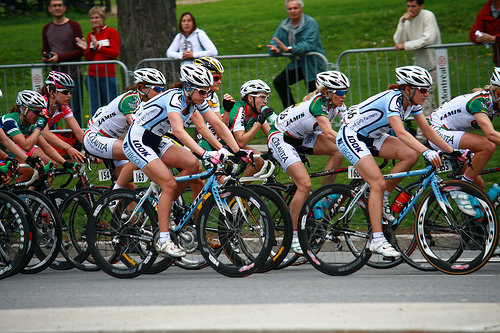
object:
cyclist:
[427, 66, 499, 222]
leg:
[84, 76, 101, 118]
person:
[76, 7, 120, 116]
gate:
[226, 54, 416, 106]